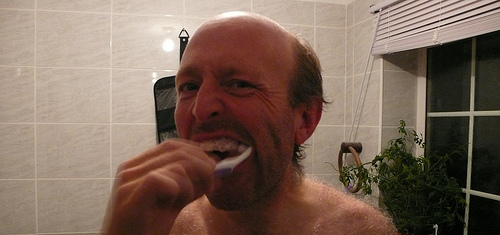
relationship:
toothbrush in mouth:
[200, 145, 258, 177] [180, 122, 250, 170]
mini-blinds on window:
[368, 3, 497, 58] [428, 29, 498, 234]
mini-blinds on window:
[375, 3, 498, 45] [383, 5, 499, 221]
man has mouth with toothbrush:
[95, 12, 397, 232] [182, 111, 284, 230]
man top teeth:
[95, 12, 397, 232] [188, 138, 252, 157]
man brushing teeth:
[95, 12, 397, 232] [193, 136, 251, 163]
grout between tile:
[17, 63, 71, 128] [36, 47, 184, 172]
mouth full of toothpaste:
[183, 132, 257, 175] [189, 137, 250, 162]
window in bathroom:
[413, 30, 498, 233] [0, 1, 499, 231]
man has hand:
[95, 12, 397, 232] [163, 131, 238, 182]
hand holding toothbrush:
[163, 131, 238, 182] [210, 145, 253, 183]